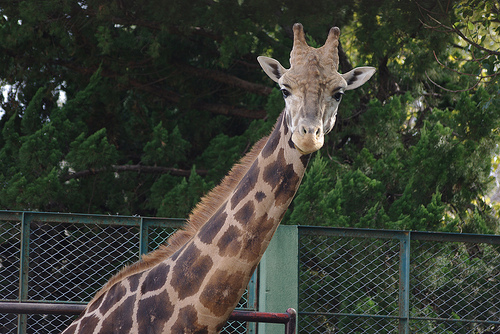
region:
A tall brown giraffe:
[130, 22, 360, 330]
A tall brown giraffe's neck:
[156, 141, 309, 291]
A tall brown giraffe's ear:
[345, 62, 380, 89]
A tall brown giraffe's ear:
[257, 50, 284, 78]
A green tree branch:
[0, 89, 174, 171]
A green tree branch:
[375, 96, 412, 215]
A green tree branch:
[17, 21, 175, 114]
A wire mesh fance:
[314, 246, 394, 318]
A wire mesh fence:
[437, 261, 477, 331]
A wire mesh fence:
[30, 226, 139, 316]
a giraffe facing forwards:
[37, 19, 384, 331]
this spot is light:
[205, 264, 242, 316]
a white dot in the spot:
[220, 280, 231, 297]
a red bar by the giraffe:
[232, 309, 303, 331]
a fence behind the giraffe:
[7, 206, 498, 332]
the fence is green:
[0, 197, 497, 329]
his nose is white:
[290, 137, 330, 157]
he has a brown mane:
[96, 122, 276, 295]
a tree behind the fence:
[24, 17, 490, 237]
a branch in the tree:
[75, 137, 218, 180]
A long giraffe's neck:
[80, 3, 387, 330]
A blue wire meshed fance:
[302, 227, 412, 320]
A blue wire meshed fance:
[412, 233, 487, 330]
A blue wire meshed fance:
[26, 209, 136, 299]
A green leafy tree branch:
[7, 137, 189, 201]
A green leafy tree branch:
[302, 159, 415, 216]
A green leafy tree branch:
[2, 35, 223, 111]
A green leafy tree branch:
[392, 15, 479, 121]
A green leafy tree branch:
[50, 14, 279, 46]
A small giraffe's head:
[265, 25, 368, 147]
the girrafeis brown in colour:
[251, 15, 470, 304]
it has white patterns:
[148, 143, 310, 329]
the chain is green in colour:
[306, 233, 469, 333]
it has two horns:
[271, 18, 358, 66]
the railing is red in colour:
[248, 302, 309, 329]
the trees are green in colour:
[371, 106, 470, 198]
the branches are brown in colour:
[75, 31, 237, 118]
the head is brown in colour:
[276, 33, 386, 171]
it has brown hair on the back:
[121, 158, 266, 245]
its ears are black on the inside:
[236, 39, 288, 83]